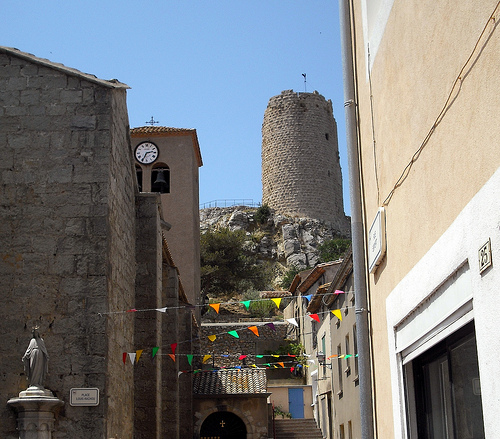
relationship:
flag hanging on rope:
[124, 302, 137, 315] [107, 302, 197, 310]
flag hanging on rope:
[157, 300, 172, 315] [129, 305, 189, 314]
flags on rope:
[291, 72, 314, 88] [102, 287, 351, 314]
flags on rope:
[291, 72, 314, 88] [115, 349, 357, 357]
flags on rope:
[291, 72, 314, 88] [123, 302, 352, 356]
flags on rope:
[291, 72, 314, 88] [192, 350, 312, 358]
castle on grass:
[253, 89, 349, 231] [203, 207, 347, 290]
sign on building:
[352, 211, 395, 263] [342, 0, 498, 439]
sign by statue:
[67, 385, 100, 405] [13, 322, 64, 394]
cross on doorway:
[141, 112, 164, 130] [197, 407, 248, 435]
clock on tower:
[132, 137, 161, 166] [125, 116, 205, 321]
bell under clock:
[145, 167, 173, 189] [132, 141, 159, 164]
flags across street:
[291, 72, 314, 88] [244, 420, 335, 436]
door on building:
[281, 385, 315, 424] [267, 377, 313, 419]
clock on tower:
[132, 137, 161, 166] [129, 122, 203, 327]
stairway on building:
[265, 403, 320, 436] [266, 378, 312, 417]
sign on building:
[352, 211, 395, 263] [342, 2, 498, 435]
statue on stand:
[13, 322, 64, 394] [8, 396, 63, 436]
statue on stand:
[21, 324, 49, 391] [6, 386, 64, 432]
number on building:
[464, 241, 494, 272] [342, 2, 498, 435]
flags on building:
[291, 72, 314, 88] [342, 2, 498, 435]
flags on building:
[291, 72, 314, 88] [2, 42, 201, 436]